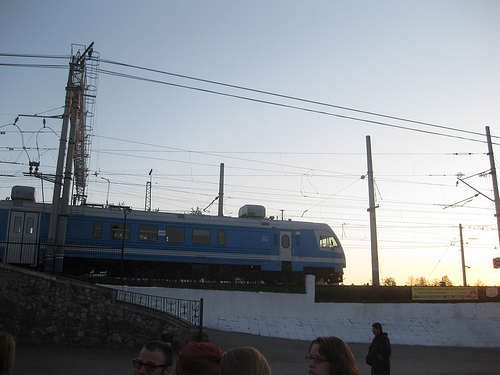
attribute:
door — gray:
[5, 207, 49, 279]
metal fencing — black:
[60, 270, 212, 330]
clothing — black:
[366, 331, 391, 369]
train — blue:
[2, 189, 358, 304]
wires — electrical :
[98, 93, 482, 240]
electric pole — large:
[362, 126, 382, 283]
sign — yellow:
[409, 281, 480, 301]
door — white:
[275, 228, 299, 261]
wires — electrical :
[4, 47, 498, 265]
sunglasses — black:
[135, 359, 159, 372]